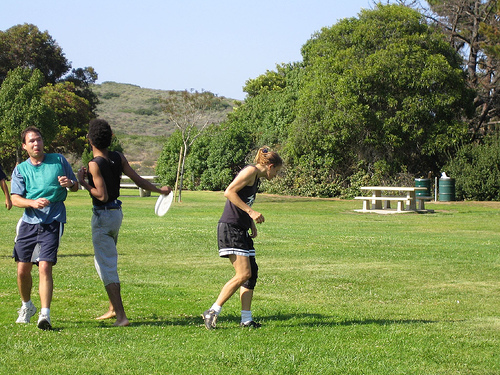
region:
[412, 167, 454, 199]
Two large garbage cans.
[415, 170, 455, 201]
Two green garbage bins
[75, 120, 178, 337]
Barefooted person playing frisbee.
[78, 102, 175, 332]
Person with white frisbee.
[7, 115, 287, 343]
Three people playing in a field.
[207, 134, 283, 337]
Woman in black shorts with white stripes.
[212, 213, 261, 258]
Black shorts with two white strips.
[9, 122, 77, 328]
Man with blue shorts.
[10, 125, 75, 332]
Man wearing blue and green top.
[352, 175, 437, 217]
Stone table with two benches.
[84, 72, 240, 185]
A hill.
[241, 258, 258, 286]
A black knee brace.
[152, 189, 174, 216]
A white frisbee.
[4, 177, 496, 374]
Green grass with light spots.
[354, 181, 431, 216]
A white cement picnic table.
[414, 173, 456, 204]
Green trash barrels.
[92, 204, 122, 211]
A dark colored belt.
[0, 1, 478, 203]
Green leafy trees.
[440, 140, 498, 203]
A green bush.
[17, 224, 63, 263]
A pair of blue shorts with a white stripe down the side.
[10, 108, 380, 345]
men are playing frisbee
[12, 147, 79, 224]
man's shirt is blue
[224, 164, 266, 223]
man's shirt is black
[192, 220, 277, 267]
man's shorts are black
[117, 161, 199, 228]
man holding a frisbee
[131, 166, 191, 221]
the frisbee is white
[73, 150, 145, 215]
man's shirt is black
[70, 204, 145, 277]
man is wearing capris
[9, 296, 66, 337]
man's shoes are white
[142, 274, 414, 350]
shadow of men on ground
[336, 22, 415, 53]
green leaves on brown branches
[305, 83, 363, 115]
green leaves on brown branches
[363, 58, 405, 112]
green leaves on brown branches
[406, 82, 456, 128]
green leaves on brown branches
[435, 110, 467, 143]
green leaves on brown branches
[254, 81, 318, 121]
green leaves on brown branches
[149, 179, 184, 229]
white Frisbee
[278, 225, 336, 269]
short green and brown grass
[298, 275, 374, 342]
short green and brown grass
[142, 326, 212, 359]
short green and brown grass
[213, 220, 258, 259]
women's black shorts with white stripes at the leg hem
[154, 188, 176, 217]
white frisbee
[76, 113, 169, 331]
light skinned bare foot female play fighting with the guy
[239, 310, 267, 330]
white sock slouched a quarter up the calf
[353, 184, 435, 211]
cement picnic table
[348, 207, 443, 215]
cement foundation for the cement table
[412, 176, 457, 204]
two green metal barrels used for garbage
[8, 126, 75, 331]
guy backing up because the female is play fighting with him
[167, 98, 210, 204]
newly planted tree that's bare as a baby's head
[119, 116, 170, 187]
opening in the trees for people to walk back there